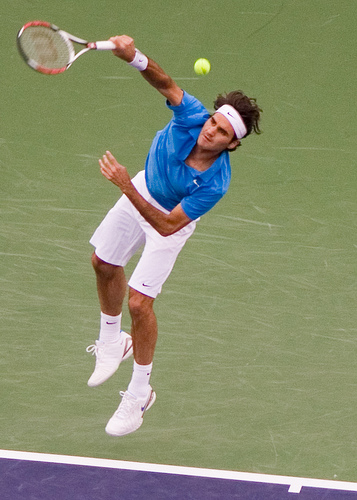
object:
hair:
[212, 89, 263, 152]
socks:
[99, 310, 124, 340]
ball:
[193, 57, 211, 78]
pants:
[88, 167, 195, 301]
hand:
[109, 33, 135, 63]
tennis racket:
[15, 19, 120, 73]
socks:
[128, 357, 152, 392]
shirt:
[143, 89, 231, 226]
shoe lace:
[86, 343, 100, 363]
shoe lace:
[119, 388, 138, 418]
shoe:
[86, 329, 133, 387]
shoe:
[103, 383, 156, 436]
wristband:
[125, 48, 147, 71]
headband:
[214, 104, 249, 139]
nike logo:
[227, 112, 233, 118]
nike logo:
[141, 401, 149, 413]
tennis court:
[0, 0, 357, 500]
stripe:
[0, 448, 357, 492]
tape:
[95, 40, 117, 48]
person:
[90, 31, 264, 438]